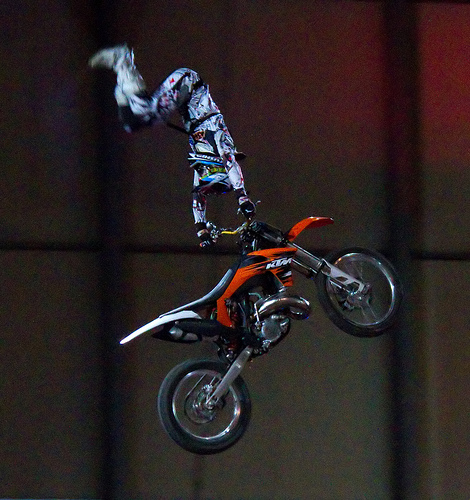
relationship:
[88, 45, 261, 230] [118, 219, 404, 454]
rider on motorbike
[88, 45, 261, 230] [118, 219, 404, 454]
professional rider working motorbike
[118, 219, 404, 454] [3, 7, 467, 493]
motorbike in air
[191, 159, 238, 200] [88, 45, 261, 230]
helmet on rider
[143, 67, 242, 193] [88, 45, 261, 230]
uniform of rider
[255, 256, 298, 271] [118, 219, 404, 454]
logo on motorbike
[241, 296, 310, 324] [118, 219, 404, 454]
exhaust pipe on motorbike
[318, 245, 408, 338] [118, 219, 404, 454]
front wheel of motorbike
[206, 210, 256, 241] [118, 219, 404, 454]
handlebars on motorbike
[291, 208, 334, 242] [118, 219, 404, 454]
front fender on motorbike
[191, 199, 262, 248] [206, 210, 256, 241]
hands holding handlebars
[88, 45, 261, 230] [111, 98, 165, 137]
rider bending knees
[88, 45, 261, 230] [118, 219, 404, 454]
rider holding motorbike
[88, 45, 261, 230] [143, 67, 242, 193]
rider in uniform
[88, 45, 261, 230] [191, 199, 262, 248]
rider wearing gloves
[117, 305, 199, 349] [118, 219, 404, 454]
tail on motorbike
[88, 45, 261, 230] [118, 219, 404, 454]
rider jumping motorbike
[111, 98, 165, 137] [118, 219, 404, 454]
knees bent motorbike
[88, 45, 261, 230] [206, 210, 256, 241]
rider holding handlebars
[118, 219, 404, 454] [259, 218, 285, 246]
motorbike has lights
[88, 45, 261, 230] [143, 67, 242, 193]
rider wearing uniform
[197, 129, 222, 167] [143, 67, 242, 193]
person image on outfit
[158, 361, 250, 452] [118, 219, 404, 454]
lower wheel on motorbike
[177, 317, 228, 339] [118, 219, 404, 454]
points on motorbike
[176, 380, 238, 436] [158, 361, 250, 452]
spokes on lower wheel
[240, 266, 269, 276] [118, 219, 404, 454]
trim on motorbike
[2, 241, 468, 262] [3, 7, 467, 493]
large line on wall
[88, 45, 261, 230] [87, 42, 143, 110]
rider has boots